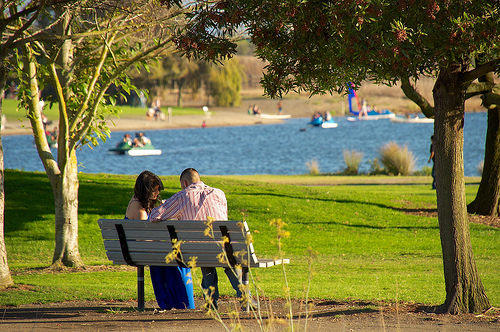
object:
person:
[201, 121, 206, 128]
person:
[276, 101, 282, 114]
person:
[253, 103, 261, 115]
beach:
[0, 97, 279, 134]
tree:
[1, 0, 185, 270]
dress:
[123, 170, 195, 310]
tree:
[176, 0, 500, 314]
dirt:
[365, 294, 471, 330]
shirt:
[149, 181, 229, 222]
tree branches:
[68, 27, 182, 150]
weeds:
[156, 204, 330, 329]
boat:
[106, 146, 162, 156]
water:
[155, 129, 430, 148]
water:
[2, 109, 498, 176]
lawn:
[0, 93, 498, 313]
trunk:
[399, 58, 499, 315]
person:
[120, 133, 133, 147]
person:
[132, 131, 151, 148]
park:
[15, 21, 499, 286]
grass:
[296, 197, 404, 268]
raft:
[347, 81, 364, 121]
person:
[359, 97, 369, 120]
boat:
[346, 109, 395, 122]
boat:
[307, 122, 338, 129]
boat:
[390, 116, 436, 124]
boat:
[260, 113, 291, 119]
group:
[118, 132, 152, 149]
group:
[358, 97, 386, 120]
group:
[312, 109, 332, 121]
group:
[248, 103, 262, 114]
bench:
[97, 218, 291, 311]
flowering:
[355, 6, 421, 63]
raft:
[108, 148, 123, 154]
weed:
[268, 213, 302, 329]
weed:
[292, 242, 319, 330]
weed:
[200, 215, 260, 330]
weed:
[164, 239, 234, 330]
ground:
[6, 174, 497, 329]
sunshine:
[28, 182, 498, 302]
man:
[150, 167, 261, 312]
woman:
[122, 170, 193, 311]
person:
[123, 170, 194, 311]